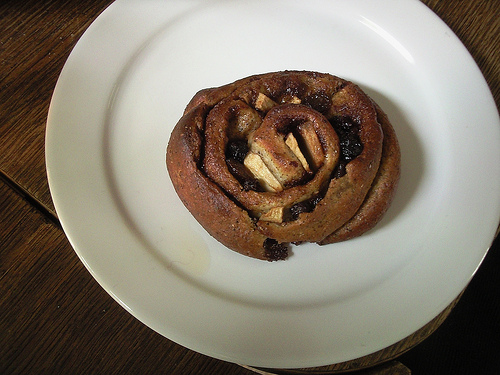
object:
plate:
[44, 2, 499, 368]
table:
[1, 0, 499, 375]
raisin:
[223, 134, 247, 161]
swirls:
[194, 93, 358, 213]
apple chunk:
[238, 152, 283, 194]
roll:
[161, 67, 402, 262]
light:
[358, 17, 416, 66]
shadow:
[339, 82, 426, 237]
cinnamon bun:
[163, 66, 403, 262]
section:
[0, 174, 259, 374]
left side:
[40, 0, 170, 344]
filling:
[330, 112, 363, 180]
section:
[43, 1, 500, 369]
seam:
[0, 168, 60, 229]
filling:
[241, 152, 281, 193]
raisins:
[287, 198, 312, 222]